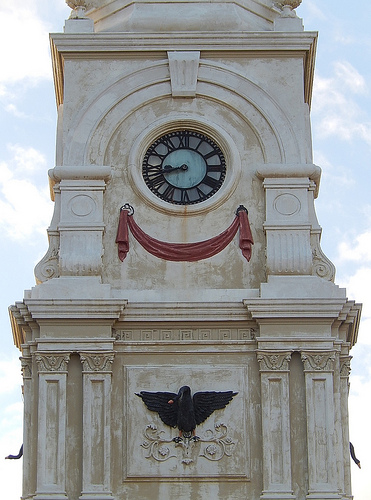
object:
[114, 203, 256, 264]
banner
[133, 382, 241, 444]
swan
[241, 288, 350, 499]
pillar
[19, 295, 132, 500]
pillar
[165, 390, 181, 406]
beak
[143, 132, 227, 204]
face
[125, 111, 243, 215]
clock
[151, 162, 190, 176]
hour hand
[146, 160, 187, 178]
minute hand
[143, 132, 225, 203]
roman numerals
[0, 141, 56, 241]
clouds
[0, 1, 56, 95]
clouds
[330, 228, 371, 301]
clouds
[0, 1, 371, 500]
sky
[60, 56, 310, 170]
arch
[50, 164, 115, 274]
column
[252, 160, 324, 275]
column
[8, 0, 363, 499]
monument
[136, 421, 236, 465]
leaves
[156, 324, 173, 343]
boxes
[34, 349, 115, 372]
design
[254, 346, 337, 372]
design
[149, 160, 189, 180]
hands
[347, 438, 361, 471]
bird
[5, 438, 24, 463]
bird